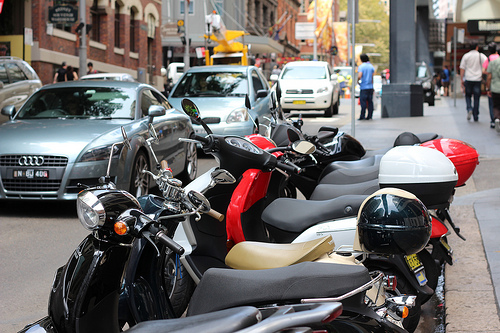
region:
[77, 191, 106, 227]
A light on the front of a scooter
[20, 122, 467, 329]
Scooters parked in a row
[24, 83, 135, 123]
The windshield of a car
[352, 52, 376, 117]
A man in blue standing by the road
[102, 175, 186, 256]
The handlebars of the scooter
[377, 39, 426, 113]
A large metal support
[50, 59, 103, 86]
People standing in a group on the sidewalk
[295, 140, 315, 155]
A side mirror on a scooter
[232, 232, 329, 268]
The gold seat of a scooter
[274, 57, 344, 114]
A white vehicle in the street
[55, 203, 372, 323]
motorcyle on the sidewalk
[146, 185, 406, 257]
motorcyle on the sidewalk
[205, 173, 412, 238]
motorcyle on the sidewalk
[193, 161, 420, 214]
motorcyle on the sidewalk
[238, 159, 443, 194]
motorcyle on the sidewalk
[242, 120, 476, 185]
motorcyle on the sidewalk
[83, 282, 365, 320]
motorcyle on the sidewalk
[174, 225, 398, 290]
motorcyle on the sidewalk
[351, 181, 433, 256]
black motorcycle helmet on vehicle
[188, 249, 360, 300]
black seat on motorcycle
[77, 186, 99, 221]
front light of motorcycle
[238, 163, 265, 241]
red frame of bike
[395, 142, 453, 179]
white lid on case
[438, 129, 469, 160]
red carrying case on back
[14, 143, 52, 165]
logo on front of car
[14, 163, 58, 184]
licence plate on car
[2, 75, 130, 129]
front wind shield on car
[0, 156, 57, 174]
grill on front of car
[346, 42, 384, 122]
person standing next to the car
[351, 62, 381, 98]
person wearing blue shirt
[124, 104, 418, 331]
motorcycles by the road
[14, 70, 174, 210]
car driving down the road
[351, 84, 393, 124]
man is wearing jeans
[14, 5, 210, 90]
buildings next to the road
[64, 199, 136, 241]
light on the motorcycle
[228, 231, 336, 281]
seat of the motorcycle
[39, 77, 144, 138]
window on the car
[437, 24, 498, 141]
people walking on the sidewalk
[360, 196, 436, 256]
helmet on a cycle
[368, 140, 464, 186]
storage on a cycle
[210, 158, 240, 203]
mirror on a cycle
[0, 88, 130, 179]
car on a street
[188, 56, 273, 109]
car on a street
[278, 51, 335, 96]
car on a street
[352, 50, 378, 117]
man wearing blue shirt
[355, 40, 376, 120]
man wearing blue jeans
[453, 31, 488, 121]
man wearing white shirt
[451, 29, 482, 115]
man wearing blue jeans